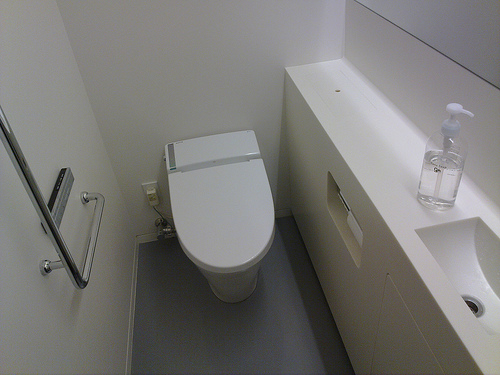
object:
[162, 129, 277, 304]
toilet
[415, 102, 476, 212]
bottle of soap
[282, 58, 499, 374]
counter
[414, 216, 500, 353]
sink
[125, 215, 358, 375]
floor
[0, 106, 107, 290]
chrome bar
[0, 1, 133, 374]
wall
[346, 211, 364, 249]
toilet roll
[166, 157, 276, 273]
toilet seat lid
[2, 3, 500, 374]
bathroom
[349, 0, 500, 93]
line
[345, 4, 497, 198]
wall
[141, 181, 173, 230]
outlet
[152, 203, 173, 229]
wire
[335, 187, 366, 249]
toilet paper holder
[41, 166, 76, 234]
deodorizer